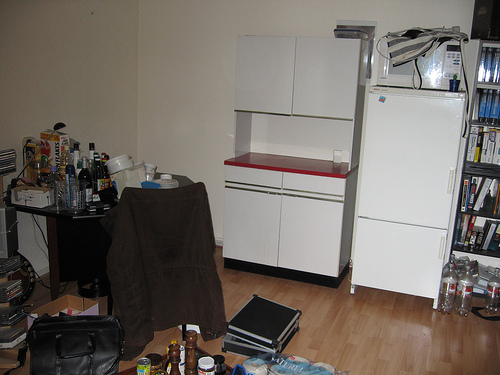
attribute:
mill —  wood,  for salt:
[165, 341, 182, 373]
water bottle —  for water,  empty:
[458, 267, 470, 314]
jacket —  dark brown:
[98, 170, 232, 355]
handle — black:
[55, 328, 97, 360]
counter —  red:
[221, 148, 356, 180]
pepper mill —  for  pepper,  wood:
[172, 326, 199, 371]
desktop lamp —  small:
[13, 112, 70, 214]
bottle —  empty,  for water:
[445, 255, 475, 317]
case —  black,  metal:
[217, 295, 305, 355]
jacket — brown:
[104, 180, 226, 361]